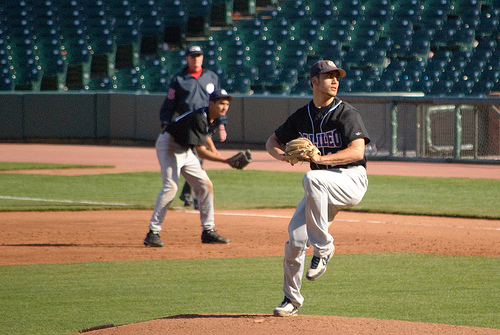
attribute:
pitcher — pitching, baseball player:
[264, 61, 370, 315]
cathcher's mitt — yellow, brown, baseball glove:
[282, 137, 321, 165]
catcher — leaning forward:
[141, 90, 252, 248]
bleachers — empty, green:
[1, 1, 498, 98]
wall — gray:
[1, 91, 498, 161]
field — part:
[2, 139, 499, 334]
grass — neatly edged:
[0, 162, 499, 220]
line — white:
[1, 193, 499, 237]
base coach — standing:
[157, 45, 221, 132]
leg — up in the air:
[299, 169, 366, 277]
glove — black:
[228, 148, 253, 170]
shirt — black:
[273, 97, 370, 168]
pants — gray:
[281, 162, 368, 307]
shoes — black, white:
[306, 252, 335, 281]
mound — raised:
[74, 312, 499, 335]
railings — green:
[387, 100, 414, 159]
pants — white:
[146, 132, 219, 231]